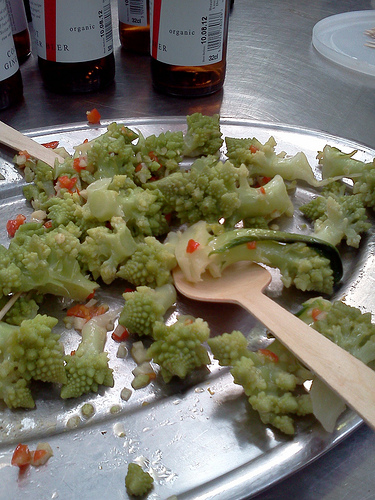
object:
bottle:
[149, 1, 230, 96]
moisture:
[124, 401, 224, 460]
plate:
[2, 115, 375, 500]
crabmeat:
[0, 113, 375, 436]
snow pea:
[205, 228, 343, 295]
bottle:
[29, 0, 115, 94]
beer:
[150, 0, 230, 99]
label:
[150, 1, 222, 66]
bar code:
[207, 11, 223, 51]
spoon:
[171, 261, 375, 433]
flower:
[6, 114, 373, 433]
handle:
[237, 295, 375, 430]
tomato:
[85, 108, 101, 122]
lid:
[312, 1, 375, 76]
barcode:
[103, 5, 113, 43]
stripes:
[43, 0, 57, 64]